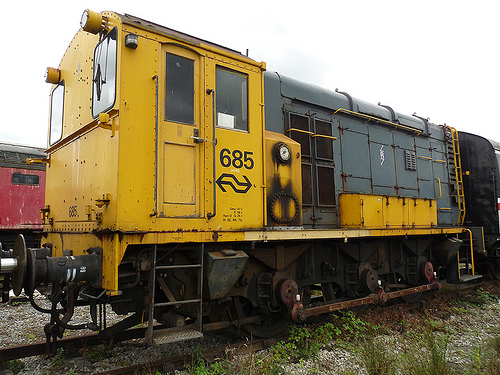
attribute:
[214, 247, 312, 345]
wheels — rusty, metal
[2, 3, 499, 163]
sky — bright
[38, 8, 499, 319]
train — yellow, black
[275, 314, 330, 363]
weed — green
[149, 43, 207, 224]
door — yellow, closed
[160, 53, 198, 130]
window — glass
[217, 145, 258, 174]
numbers — black, 685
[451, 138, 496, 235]
engine — black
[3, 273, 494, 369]
track — rusty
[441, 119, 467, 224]
ladder — yellow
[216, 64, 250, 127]
window — glass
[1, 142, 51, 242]
train — red